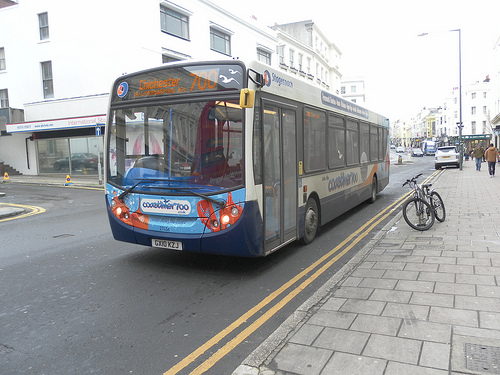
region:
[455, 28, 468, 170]
tall gray lamp post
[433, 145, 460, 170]
car parked next to lamp post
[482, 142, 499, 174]
person walking on sidewalk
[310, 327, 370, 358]
brick on sidewalk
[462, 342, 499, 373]
metal grate on sidewalk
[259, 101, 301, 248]
glass door on bus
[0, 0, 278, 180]
white building behind bus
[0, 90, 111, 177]
storefront behind bus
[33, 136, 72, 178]
large glass windows on storefront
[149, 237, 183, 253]
license plate on bus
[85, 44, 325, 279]
the front of the bus is blue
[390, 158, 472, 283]
this is a bike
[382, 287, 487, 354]
the sidewalk is bricked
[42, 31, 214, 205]
the building is white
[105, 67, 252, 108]
the bus is route 700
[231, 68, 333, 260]
the doorway to the bus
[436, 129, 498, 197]
people walking down the street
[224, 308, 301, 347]
the road lines are yellow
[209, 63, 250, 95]
the two seagulls are white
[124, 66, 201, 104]
the route is to chichester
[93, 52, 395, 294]
bus on city street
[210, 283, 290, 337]
yellow lines painted on street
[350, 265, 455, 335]
grey bricks form sidewalk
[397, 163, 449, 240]
bike on sidewalk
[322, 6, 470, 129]
buildings in background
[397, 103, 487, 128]
background is overexposed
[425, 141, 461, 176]
car parked halfway on sidewalk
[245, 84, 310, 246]
door to enter the bus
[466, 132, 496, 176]
people walking on the sidewalk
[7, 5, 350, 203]
white building behind the bus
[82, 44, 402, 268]
a bus on a street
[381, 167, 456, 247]
a bike is in the street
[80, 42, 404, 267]
bus is blue and yellow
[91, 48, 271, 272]
front of bus is blue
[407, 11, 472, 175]
a tall light pole on sidewalk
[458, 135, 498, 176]
people walking on sidewalk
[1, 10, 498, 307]
a bus in a city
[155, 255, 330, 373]
two double lines in the road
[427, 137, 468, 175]
a car with two wheels on sidewalk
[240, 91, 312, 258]
big door of bus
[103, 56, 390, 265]
a public bus is in the street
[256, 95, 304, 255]
the doors are closed on the bus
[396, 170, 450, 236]
a bike is parked on the sidewalk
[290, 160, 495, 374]
the sidewalk is tiled by the street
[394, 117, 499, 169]
pedestrians are walking on the side of the street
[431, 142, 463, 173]
a car is parked half in the street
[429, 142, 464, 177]
the car is parked half on the sidewalk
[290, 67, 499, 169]
buildings line the street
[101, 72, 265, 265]
the front of the bus is blue and red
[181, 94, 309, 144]
the buses interior lights are on